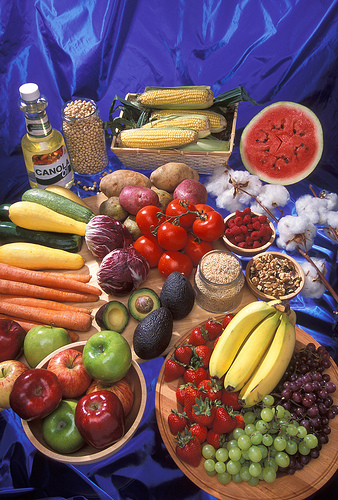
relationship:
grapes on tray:
[199, 395, 318, 487] [152, 309, 338, 498]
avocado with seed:
[124, 286, 163, 322] [132, 293, 154, 313]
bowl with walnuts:
[243, 248, 305, 303] [251, 254, 291, 293]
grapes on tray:
[279, 341, 326, 445] [152, 309, 338, 498]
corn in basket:
[134, 81, 213, 112] [110, 90, 239, 174]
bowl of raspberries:
[221, 208, 277, 258] [225, 205, 271, 248]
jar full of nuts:
[57, 95, 108, 174] [74, 135, 96, 163]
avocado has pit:
[126, 286, 163, 322] [134, 291, 154, 312]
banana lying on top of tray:
[238, 309, 296, 414] [152, 309, 326, 497]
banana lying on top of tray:
[207, 298, 275, 380] [152, 309, 326, 497]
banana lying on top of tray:
[222, 308, 280, 394] [152, 309, 326, 497]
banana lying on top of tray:
[235, 309, 296, 409] [152, 309, 326, 497]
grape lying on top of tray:
[202, 443, 217, 459] [152, 309, 326, 497]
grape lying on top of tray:
[211, 459, 227, 474] [152, 309, 326, 497]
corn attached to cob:
[134, 87, 213, 102] [134, 95, 141, 101]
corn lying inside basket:
[134, 87, 213, 102] [110, 90, 239, 174]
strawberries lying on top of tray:
[175, 430, 204, 469] [152, 309, 326, 497]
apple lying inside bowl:
[8, 365, 63, 419] [20, 339, 147, 464]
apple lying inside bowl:
[40, 397, 87, 452] [20, 339, 147, 464]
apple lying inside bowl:
[73, 388, 127, 448] [20, 339, 147, 464]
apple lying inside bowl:
[80, 329, 133, 383] [20, 339, 147, 464]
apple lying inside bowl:
[45, 348, 92, 397] [20, 339, 147, 464]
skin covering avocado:
[131, 305, 174, 360] [131, 306, 174, 360]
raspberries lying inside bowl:
[249, 228, 262, 242] [221, 211, 275, 257]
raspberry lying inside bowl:
[245, 222, 254, 229] [221, 211, 275, 257]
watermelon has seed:
[237, 100, 325, 191] [273, 124, 276, 129]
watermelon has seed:
[237, 100, 325, 191] [255, 138, 260, 142]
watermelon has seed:
[237, 100, 325, 191] [298, 142, 304, 146]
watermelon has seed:
[237, 100, 325, 191] [291, 128, 297, 134]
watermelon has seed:
[237, 100, 325, 191] [271, 162, 276, 166]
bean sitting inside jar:
[72, 109, 76, 114] [60, 96, 110, 177]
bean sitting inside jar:
[76, 113, 81, 117] [60, 96, 110, 177]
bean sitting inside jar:
[84, 145, 88, 149] [60, 96, 110, 177]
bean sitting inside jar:
[74, 152, 78, 157] [60, 96, 110, 177]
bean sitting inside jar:
[86, 162, 91, 165] [60, 96, 110, 177]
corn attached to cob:
[134, 81, 213, 112] [134, 94, 142, 101]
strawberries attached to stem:
[175, 430, 204, 469] [172, 425, 195, 448]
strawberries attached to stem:
[175, 430, 204, 469] [167, 408, 189, 420]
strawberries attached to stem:
[175, 430, 204, 469] [168, 353, 187, 365]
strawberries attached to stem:
[175, 430, 204, 469] [171, 341, 192, 347]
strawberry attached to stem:
[186, 325, 208, 344] [198, 323, 210, 340]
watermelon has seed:
[237, 100, 325, 191] [261, 138, 267, 143]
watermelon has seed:
[237, 100, 325, 191] [255, 138, 259, 142]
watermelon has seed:
[237, 100, 325, 191] [271, 162, 275, 166]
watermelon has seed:
[237, 100, 325, 191] [292, 128, 296, 133]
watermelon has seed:
[237, 100, 325, 191] [298, 132, 304, 137]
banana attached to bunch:
[207, 298, 275, 380] [208, 298, 297, 407]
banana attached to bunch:
[222, 308, 280, 394] [208, 298, 297, 407]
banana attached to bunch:
[235, 309, 296, 409] [208, 298, 297, 407]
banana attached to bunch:
[238, 309, 296, 414] [208, 298, 297, 407]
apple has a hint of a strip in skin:
[47, 348, 93, 400] [62, 370, 85, 392]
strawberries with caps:
[169, 368, 229, 462] [193, 373, 236, 424]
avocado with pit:
[126, 286, 163, 322] [136, 295, 153, 312]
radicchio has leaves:
[84, 214, 148, 298] [95, 220, 129, 279]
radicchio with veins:
[84, 214, 148, 298] [85, 224, 111, 268]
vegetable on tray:
[1, 261, 103, 296] [2, 184, 259, 354]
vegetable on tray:
[97, 193, 128, 226] [2, 184, 259, 354]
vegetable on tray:
[1, 264, 101, 299] [0, 185, 266, 371]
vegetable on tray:
[97, 193, 128, 221] [0, 185, 266, 371]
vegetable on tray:
[148, 161, 199, 192] [2, 184, 259, 354]